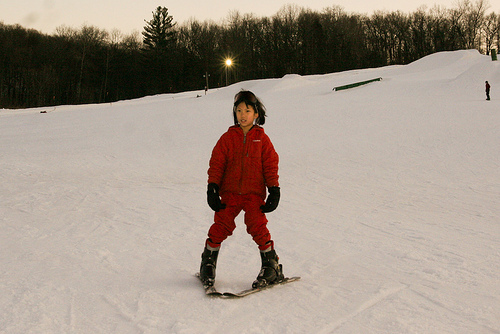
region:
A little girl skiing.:
[166, 84, 317, 296]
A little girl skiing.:
[177, 85, 307, 302]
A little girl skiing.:
[170, 76, 320, 306]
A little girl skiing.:
[161, 80, 320, 308]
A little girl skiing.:
[166, 82, 328, 320]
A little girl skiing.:
[164, 80, 318, 304]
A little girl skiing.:
[170, 80, 332, 315]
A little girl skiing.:
[170, 77, 327, 310]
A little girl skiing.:
[153, 80, 307, 300]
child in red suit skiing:
[197, 83, 304, 305]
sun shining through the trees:
[205, 48, 246, 75]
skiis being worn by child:
[193, 235, 303, 311]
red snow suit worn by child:
[176, 112, 294, 258]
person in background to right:
[468, 72, 498, 108]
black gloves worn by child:
[189, 177, 294, 220]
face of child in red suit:
[213, 78, 281, 139]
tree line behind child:
[10, 20, 492, 87]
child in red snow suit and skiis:
[192, 87, 317, 315]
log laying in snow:
[325, 75, 388, 97]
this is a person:
[88, 84, 312, 308]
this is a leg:
[191, 205, 241, 284]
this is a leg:
[241, 212, 305, 299]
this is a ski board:
[185, 250, 228, 300]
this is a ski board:
[231, 211, 308, 299]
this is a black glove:
[201, 184, 232, 219]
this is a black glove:
[256, 181, 301, 218]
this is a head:
[213, 82, 291, 135]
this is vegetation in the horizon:
[6, 1, 464, 84]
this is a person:
[473, 70, 499, 119]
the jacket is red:
[201, 122, 286, 244]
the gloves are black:
[205, 185, 225, 211]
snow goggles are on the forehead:
[226, 85, 261, 107]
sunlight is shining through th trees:
[216, 53, 248, 70]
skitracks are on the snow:
[330, 280, 388, 329]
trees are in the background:
[223, 18, 400, 66]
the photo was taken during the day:
[9, 9, 487, 326]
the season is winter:
[5, 3, 495, 330]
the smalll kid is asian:
[198, 84, 319, 300]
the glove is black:
[206, 178, 225, 210]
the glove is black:
[259, 187, 280, 212]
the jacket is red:
[207, 123, 279, 193]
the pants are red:
[208, 191, 270, 249]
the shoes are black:
[199, 238, 283, 286]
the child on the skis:
[193, 89, 300, 297]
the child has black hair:
[198, 89, 285, 288]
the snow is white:
[1, 48, 499, 333]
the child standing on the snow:
[1, 48, 498, 332]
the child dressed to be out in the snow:
[195, 88, 300, 296]